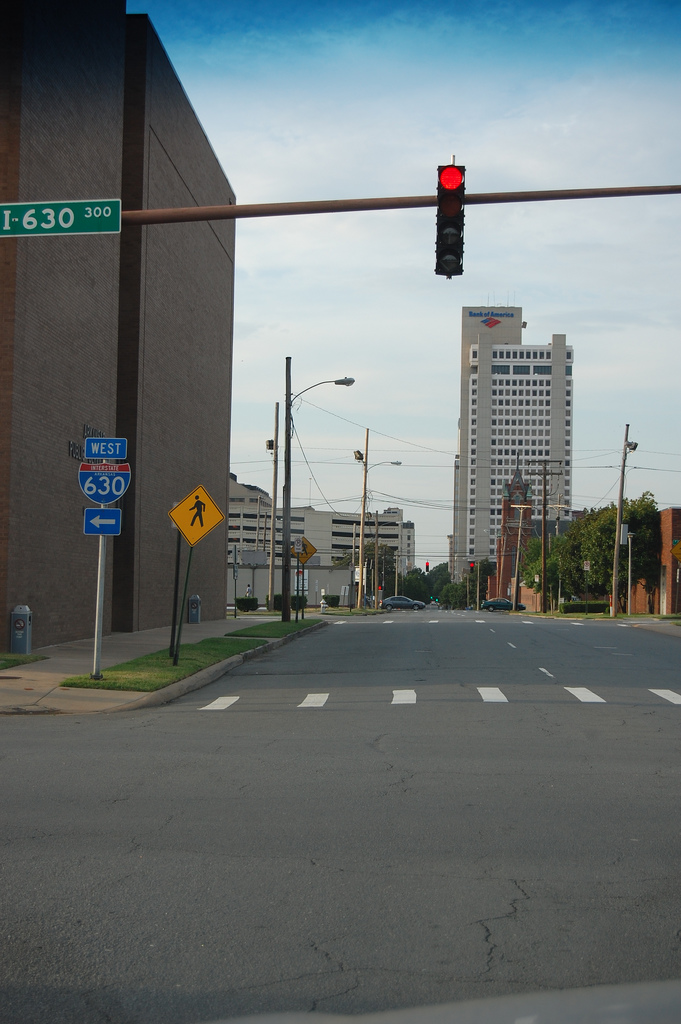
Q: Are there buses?
A: No, there are no buses.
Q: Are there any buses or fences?
A: No, there are no buses or fences.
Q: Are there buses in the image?
A: No, there are no buses.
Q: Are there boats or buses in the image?
A: No, there are no buses or boats.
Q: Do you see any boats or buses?
A: No, there are no buses or boats.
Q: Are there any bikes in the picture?
A: No, there are no bikes.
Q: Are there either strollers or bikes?
A: No, there are no bikes or strollers.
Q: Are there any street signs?
A: Yes, there is a street sign.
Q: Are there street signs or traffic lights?
A: Yes, there is a street sign.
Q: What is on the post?
A: The street sign is on the post.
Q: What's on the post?
A: The street sign is on the post.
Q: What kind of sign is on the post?
A: The sign is a street sign.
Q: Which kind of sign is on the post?
A: The sign is a street sign.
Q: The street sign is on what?
A: The street sign is on the post.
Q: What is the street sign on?
A: The street sign is on the post.